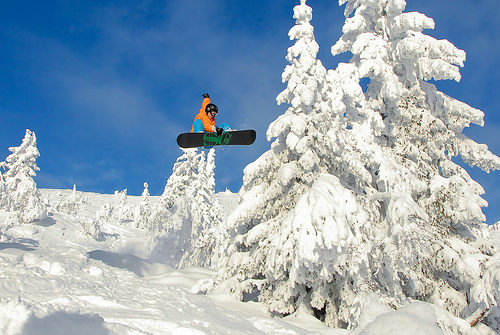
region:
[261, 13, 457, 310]
tree branches weighed down by snow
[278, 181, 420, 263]
white snow on tree branches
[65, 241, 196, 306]
fresh snow on the ground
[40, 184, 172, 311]
snow covered ground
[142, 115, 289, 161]
black and green snow board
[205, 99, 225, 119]
black helmet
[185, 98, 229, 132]
an orange winter coat on the snow boarder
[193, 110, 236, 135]
blue snow boarding pants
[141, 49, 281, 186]
a snowboarder doing a trick in the air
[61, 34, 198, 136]
a dark blue sky with clouds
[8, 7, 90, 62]
this is the sky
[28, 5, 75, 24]
the sky is blue in color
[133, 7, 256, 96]
the sky is full of clouds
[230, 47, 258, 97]
the clouds are white in color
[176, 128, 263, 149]
this is a snowboard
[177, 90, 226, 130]
this is a man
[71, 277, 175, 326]
this is the ground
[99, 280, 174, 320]
the ground is full of snow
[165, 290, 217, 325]
the snow is white in color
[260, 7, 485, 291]
this is a tree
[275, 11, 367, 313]
A tree covered by snow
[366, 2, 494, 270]
A tree covered by snow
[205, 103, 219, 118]
A black sky diving helmet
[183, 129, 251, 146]
A black skitting board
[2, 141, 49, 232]
A short tree covered by snow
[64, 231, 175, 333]
Ground covered by snow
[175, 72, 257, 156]
A man enjoying sky diving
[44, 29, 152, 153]
Sky blue clouds at the sky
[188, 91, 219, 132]
An orange skiing suit with light blue arms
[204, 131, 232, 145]
label of the sketting board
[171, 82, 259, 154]
man doing stunt on snowboard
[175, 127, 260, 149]
black and green bottom of snowboard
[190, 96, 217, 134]
orange ski jacket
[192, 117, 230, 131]
turquoise ski pants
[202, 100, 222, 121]
black helmet on man's head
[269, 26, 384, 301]
snow covered pine tree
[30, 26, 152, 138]
clear dark blue sky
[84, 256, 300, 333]
snow covered mountain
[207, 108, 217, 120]
goggles on man's face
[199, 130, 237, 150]
green writing on snowboard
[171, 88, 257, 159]
Snowboarder airborne holding onto board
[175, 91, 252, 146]
Person on snowboard w/orange top and blue pants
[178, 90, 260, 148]
Snowboarder with black helmet on head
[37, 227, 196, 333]
Bright and white snowy hill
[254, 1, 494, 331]
Two tall trees covered in thick coat of snow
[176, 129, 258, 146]
Black snowboard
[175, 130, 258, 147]
Snowboard with green logo on bottom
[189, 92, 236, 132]
Orange shirt, blue pants, and black helmet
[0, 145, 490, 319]
Thick layers of snow on hill and its trees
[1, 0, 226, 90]
Vibrant blue sky with thin sheets of clouds